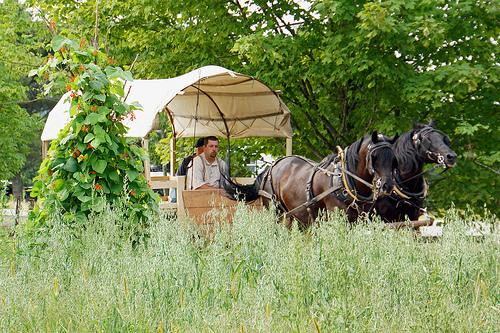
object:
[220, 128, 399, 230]
horse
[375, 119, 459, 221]
horse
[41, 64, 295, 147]
canopy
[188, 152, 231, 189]
shirt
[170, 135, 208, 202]
man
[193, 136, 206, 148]
hat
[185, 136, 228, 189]
man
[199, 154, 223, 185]
suspenders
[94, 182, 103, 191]
berries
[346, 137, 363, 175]
hair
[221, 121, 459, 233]
horses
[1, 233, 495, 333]
grass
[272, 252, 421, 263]
hooves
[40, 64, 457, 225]
wagon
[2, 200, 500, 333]
field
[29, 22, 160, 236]
plant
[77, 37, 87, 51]
flowers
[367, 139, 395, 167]
halter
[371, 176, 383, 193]
bit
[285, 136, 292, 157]
wood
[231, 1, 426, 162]
tree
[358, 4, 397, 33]
leaves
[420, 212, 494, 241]
truck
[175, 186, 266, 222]
bench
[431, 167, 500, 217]
shrubs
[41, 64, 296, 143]
roof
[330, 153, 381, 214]
harness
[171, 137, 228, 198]
people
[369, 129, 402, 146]
ears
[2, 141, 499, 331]
bushes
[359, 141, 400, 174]
blinder